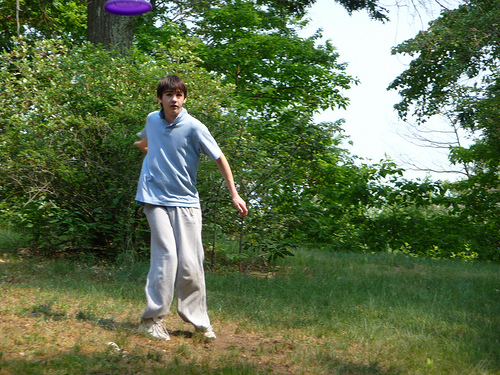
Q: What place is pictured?
A: It is a field.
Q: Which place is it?
A: It is a field.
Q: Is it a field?
A: Yes, it is a field.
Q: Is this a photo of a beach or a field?
A: It is showing a field.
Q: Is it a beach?
A: No, it is a field.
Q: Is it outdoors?
A: Yes, it is outdoors.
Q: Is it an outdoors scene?
A: Yes, it is outdoors.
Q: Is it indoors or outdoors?
A: It is outdoors.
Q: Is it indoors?
A: No, it is outdoors.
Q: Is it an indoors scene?
A: No, it is outdoors.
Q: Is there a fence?
A: No, there are no fences.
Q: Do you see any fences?
A: No, there are no fences.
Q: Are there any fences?
A: No, there are no fences.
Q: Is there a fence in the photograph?
A: No, there are no fences.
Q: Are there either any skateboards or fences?
A: No, there are no fences or skateboards.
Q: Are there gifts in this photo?
A: No, there are no gifts.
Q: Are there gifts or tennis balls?
A: No, there are no gifts or tennis balls.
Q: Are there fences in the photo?
A: No, there are no fences.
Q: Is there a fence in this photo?
A: No, there are no fences.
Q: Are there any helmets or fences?
A: No, there are no fences or helmets.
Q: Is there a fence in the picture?
A: No, there are no fences.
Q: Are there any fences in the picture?
A: No, there are no fences.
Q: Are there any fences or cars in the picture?
A: No, there are no fences or cars.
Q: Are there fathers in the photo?
A: No, there are no fathers.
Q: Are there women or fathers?
A: No, there are no fathers or women.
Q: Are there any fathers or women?
A: No, there are no fathers or women.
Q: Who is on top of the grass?
A: The boy is on top of the grass.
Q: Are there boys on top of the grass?
A: Yes, there is a boy on top of the grass.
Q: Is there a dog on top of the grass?
A: No, there is a boy on top of the grass.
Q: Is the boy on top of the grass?
A: Yes, the boy is on top of the grass.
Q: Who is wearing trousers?
A: The boy is wearing trousers.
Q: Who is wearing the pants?
A: The boy is wearing trousers.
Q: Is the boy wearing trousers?
A: Yes, the boy is wearing trousers.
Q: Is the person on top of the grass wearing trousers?
A: Yes, the boy is wearing trousers.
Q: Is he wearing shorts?
A: No, the boy is wearing trousers.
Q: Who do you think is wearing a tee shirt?
A: The boy is wearing a tee shirt.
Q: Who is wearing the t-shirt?
A: The boy is wearing a tee shirt.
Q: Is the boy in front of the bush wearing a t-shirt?
A: Yes, the boy is wearing a t-shirt.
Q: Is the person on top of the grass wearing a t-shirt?
A: Yes, the boy is wearing a t-shirt.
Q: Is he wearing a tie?
A: No, the boy is wearing a t-shirt.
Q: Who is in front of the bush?
A: The boy is in front of the bush.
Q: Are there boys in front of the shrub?
A: Yes, there is a boy in front of the shrub.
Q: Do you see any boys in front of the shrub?
A: Yes, there is a boy in front of the shrub.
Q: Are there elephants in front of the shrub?
A: No, there is a boy in front of the shrub.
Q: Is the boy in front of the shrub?
A: Yes, the boy is in front of the shrub.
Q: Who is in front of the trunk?
A: The boy is in front of the trunk.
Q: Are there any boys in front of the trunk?
A: Yes, there is a boy in front of the trunk.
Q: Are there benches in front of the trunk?
A: No, there is a boy in front of the trunk.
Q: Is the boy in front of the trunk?
A: Yes, the boy is in front of the trunk.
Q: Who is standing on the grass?
A: The boy is standing on the grass.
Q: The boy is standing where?
A: The boy is standing on the grass.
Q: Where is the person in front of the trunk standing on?
A: The boy is standing on the grass.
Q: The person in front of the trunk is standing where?
A: The boy is standing on the grass.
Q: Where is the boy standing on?
A: The boy is standing on the grass.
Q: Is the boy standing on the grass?
A: Yes, the boy is standing on the grass.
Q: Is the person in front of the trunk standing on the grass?
A: Yes, the boy is standing on the grass.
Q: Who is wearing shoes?
A: The boy is wearing shoes.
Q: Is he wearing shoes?
A: Yes, the boy is wearing shoes.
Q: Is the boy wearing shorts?
A: No, the boy is wearing shoes.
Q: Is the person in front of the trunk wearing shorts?
A: No, the boy is wearing shoes.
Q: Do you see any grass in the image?
A: Yes, there is grass.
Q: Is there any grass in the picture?
A: Yes, there is grass.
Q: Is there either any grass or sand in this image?
A: Yes, there is grass.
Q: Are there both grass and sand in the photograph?
A: No, there is grass but no sand.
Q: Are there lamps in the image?
A: No, there are no lamps.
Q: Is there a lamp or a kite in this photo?
A: No, there are no lamps or kites.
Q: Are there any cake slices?
A: No, there are no cake slices.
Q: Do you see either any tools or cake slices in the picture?
A: No, there are no cake slices or tools.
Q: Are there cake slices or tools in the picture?
A: No, there are no cake slices or tools.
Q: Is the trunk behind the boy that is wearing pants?
A: Yes, the trunk is behind the boy.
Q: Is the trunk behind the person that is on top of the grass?
A: Yes, the trunk is behind the boy.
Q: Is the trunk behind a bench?
A: No, the trunk is behind the boy.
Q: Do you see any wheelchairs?
A: No, there are no wheelchairs.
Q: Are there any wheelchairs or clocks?
A: No, there are no wheelchairs or clocks.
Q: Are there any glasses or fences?
A: No, there are no fences or glasses.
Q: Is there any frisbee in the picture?
A: Yes, there is a frisbee.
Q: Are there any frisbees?
A: Yes, there is a frisbee.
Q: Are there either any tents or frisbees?
A: Yes, there is a frisbee.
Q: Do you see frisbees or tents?
A: Yes, there is a frisbee.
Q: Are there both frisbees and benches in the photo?
A: No, there is a frisbee but no benches.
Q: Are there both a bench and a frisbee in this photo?
A: No, there is a frisbee but no benches.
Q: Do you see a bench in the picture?
A: No, there are no benches.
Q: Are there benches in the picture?
A: No, there are no benches.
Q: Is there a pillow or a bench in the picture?
A: No, there are no benches or pillows.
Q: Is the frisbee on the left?
A: Yes, the frisbee is on the left of the image.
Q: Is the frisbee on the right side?
A: No, the frisbee is on the left of the image.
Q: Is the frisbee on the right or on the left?
A: The frisbee is on the left of the image.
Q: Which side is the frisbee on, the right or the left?
A: The frisbee is on the left of the image.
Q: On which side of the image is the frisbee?
A: The frisbee is on the left of the image.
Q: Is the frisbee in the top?
A: Yes, the frisbee is in the top of the image.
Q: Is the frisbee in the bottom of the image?
A: No, the frisbee is in the top of the image.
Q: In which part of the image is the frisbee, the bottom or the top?
A: The frisbee is in the top of the image.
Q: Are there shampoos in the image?
A: No, there are no shampoos.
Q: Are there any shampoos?
A: No, there are no shampoos.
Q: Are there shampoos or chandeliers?
A: No, there are no shampoos or chandeliers.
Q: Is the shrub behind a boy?
A: Yes, the shrub is behind a boy.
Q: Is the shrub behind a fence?
A: No, the shrub is behind a boy.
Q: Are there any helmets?
A: No, there are no helmets.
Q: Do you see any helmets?
A: No, there are no helmets.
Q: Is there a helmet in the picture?
A: No, there are no helmets.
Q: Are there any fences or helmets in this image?
A: No, there are no helmets or fences.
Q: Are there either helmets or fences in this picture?
A: No, there are no helmets or fences.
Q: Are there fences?
A: No, there are no fences.